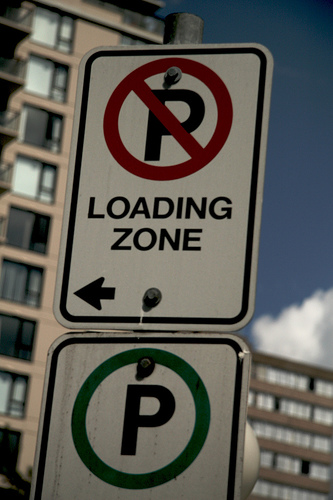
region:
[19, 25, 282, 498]
Signs on street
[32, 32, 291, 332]
Street sign is white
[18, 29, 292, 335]
Street sign has black letters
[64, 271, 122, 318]
arrow pointing left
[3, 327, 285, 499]
Arking sign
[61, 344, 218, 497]
Circle with a P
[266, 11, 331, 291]
Sky is blue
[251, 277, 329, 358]
White cloud in the blue sky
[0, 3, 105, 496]
Big building behind the signs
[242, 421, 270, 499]
Part of a light pole is round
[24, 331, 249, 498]
sign on the bottom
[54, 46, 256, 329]
sign on the top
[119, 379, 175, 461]
"P" in bottom sign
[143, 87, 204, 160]
"P" in the top sign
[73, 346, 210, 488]
green circle in bottom sign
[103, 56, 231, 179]
red circle in top sign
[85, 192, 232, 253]
"Loading Zone" in top sign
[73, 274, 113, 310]
arrow in top sign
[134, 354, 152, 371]
bolt in bottom sign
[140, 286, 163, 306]
bolt in bottom of top sign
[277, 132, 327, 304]
bright blue sky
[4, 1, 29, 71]
balconies on tall building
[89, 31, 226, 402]
two rectangle parking signs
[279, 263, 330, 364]
large white puffy clouds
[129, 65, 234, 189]
no parking allowed sign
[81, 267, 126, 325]
black arrow pointing to the left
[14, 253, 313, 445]
two brown tall buildings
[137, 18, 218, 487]
two parking signs on a pole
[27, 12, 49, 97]
long white curtains in windows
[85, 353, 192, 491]
green circle around the letter P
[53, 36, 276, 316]
sign indicating loading zone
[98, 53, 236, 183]
red circle with slash through letter P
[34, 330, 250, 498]
bottom sign on pole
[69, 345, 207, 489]
green circle around letter P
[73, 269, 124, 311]
black arrow pointing left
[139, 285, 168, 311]
bolt on bottom of sign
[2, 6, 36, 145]
balconies on tall bulding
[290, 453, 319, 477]
window with open curtain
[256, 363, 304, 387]
top floor row of windows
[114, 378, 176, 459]
black letter in circle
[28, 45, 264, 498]
The street signs are opposite of each other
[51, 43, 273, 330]
The sign has no parking listed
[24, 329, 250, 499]
Sign allows for parking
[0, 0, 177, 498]
Building is on left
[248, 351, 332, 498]
building is on the right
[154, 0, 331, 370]
The sky is blue and cloudy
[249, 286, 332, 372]
The clouds are white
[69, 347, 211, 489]
The circle is green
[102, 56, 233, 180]
The circle is red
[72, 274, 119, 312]
The arrow points to the left